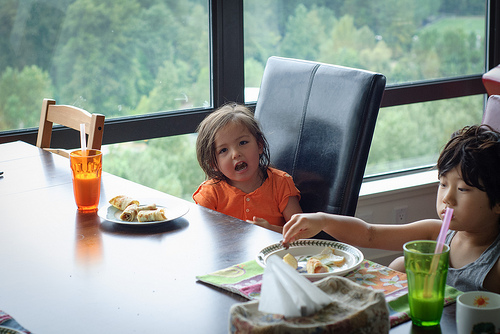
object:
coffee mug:
[452, 287, 499, 332]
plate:
[258, 235, 366, 281]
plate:
[96, 191, 188, 231]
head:
[197, 103, 267, 183]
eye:
[238, 138, 250, 146]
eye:
[217, 148, 229, 154]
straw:
[79, 122, 89, 174]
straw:
[421, 203, 459, 295]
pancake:
[108, 193, 137, 206]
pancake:
[120, 207, 136, 219]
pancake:
[137, 209, 166, 222]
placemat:
[195, 261, 267, 302]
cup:
[402, 240, 453, 327]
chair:
[253, 54, 386, 214]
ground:
[330, 124, 366, 167]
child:
[193, 104, 304, 236]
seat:
[250, 53, 383, 228]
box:
[225, 257, 390, 333]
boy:
[283, 124, 499, 291]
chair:
[481, 96, 498, 131]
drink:
[63, 145, 110, 218]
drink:
[393, 228, 462, 323]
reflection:
[265, 74, 364, 228]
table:
[0, 140, 481, 334]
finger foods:
[107, 195, 167, 220]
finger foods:
[281, 239, 296, 251]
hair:
[193, 100, 272, 186]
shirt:
[190, 167, 298, 234]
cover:
[219, 271, 391, 334]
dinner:
[255, 239, 366, 279]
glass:
[68, 149, 105, 214]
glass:
[399, 241, 454, 328]